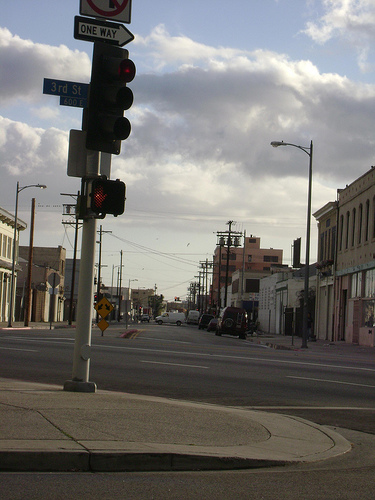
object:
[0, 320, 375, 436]
street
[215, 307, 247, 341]
van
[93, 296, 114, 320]
sign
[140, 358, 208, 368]
line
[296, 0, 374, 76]
white cloud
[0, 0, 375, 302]
sky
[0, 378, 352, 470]
sidewalk